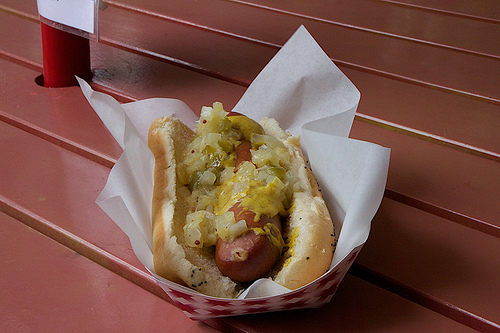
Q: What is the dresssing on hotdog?
A: Slaw.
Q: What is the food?
A: A hot dog.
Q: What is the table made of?
A: Wood.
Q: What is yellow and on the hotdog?
A: Mustard.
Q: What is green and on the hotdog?
A: Relish.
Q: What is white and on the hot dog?
A: Onions.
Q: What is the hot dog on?
A: A bun.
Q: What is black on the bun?
A: Seeds.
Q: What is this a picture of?
A: A hot dog.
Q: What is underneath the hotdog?
A: White parchment paper.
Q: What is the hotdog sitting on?
A: A table.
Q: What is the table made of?
A: Wood.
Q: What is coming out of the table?
A: A pole.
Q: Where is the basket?
A: On the table.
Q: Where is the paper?
A: On the basket.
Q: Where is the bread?
A: On the paper.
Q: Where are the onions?
A: On the hotdog.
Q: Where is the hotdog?
A: On the bun.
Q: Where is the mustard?
A: On the hot dog.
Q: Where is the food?
A: On the paper.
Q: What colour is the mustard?
A: Yellow.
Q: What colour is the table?
A: Red.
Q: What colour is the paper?
A: White.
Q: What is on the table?
A: A hotdog.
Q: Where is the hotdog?
A: On the table.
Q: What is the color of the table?
A: Red.